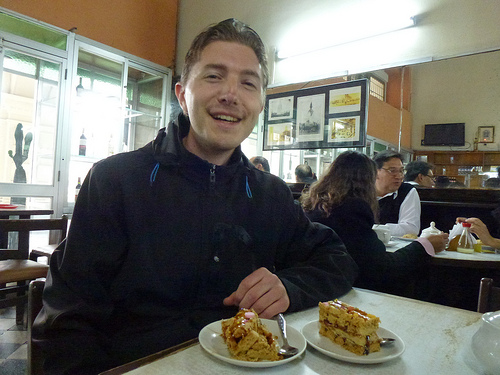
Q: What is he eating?
A: A dessert.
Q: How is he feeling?
A: Happy.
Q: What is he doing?
A: Smiling.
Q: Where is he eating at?
A: The cafe.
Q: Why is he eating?
A: He is hungry.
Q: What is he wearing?
A: A jacket.